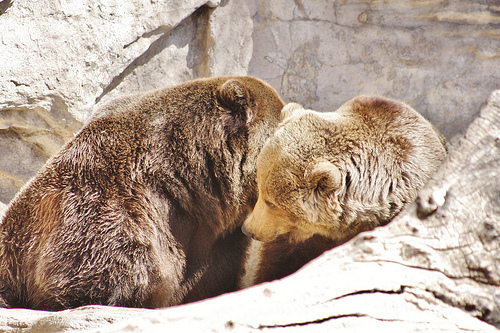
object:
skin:
[0, 73, 279, 309]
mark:
[254, 300, 427, 333]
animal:
[2, 76, 284, 307]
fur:
[0, 191, 99, 307]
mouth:
[240, 222, 274, 242]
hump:
[352, 88, 422, 133]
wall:
[0, 0, 497, 207]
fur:
[356, 121, 415, 173]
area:
[359, 231, 499, 298]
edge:
[357, 88, 497, 243]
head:
[242, 106, 359, 249]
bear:
[241, 95, 442, 248]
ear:
[303, 161, 346, 193]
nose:
[239, 225, 253, 238]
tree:
[279, 89, 500, 333]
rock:
[0, 2, 498, 189]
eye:
[264, 199, 276, 209]